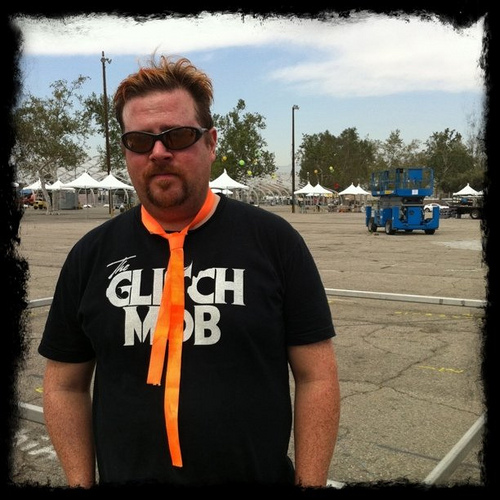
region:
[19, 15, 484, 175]
clouds in daytime sky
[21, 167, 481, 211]
white tops of tents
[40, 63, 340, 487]
man in black tee shirt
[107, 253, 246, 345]
white logo on black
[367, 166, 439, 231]
back of blue utility vehicle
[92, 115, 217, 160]
sun glasses on face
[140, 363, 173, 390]
jagged end of orange tie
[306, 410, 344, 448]
hair on man's arm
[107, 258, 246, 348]
white words on front of shirt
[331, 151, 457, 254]
blue truck in the open area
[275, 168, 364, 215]
tall white tents in the background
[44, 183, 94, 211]
porta potty in the area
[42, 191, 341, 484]
man standing wearing black tee shirt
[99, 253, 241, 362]
white writing on black tee shirt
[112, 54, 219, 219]
man has short golden brown hair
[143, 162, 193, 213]
mustach and partial beard on man's face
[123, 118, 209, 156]
man wearing dark black sunglasses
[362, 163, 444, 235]
double level blue vehicle in distance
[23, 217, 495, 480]
grey parking lot with white lines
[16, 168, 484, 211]
row of white umbrellas in background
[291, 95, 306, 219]
black street lamp with one lamp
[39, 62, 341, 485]
man in black shirt wearing a tie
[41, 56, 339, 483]
man wearing glasses has a goatee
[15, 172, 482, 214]
multiple umbrellas opened in the background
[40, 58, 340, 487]
man wearing a black tee shirt with white letters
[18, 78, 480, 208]
many trees are behind the umbrellas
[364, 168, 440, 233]
blue equipment trucked parked in the lot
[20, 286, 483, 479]
white lines are painted on the ground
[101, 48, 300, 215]
two street lights are on the lot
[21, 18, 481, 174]
faded clouds in the sky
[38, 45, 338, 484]
man's hair is blowing in the wind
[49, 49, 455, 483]
this is a man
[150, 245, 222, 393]
the tie is orange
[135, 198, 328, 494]
the shirt is black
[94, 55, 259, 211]
the man is frowning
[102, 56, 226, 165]
the hair is blonde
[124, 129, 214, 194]
the man has sunglasses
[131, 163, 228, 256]
the man has a goatee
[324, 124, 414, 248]
the vehicle is blue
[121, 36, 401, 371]
a man wearing sunglasses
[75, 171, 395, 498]
a man wearing a shirt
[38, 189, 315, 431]
a man wearing t shirt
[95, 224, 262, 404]
a man with lettering on his shirt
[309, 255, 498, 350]
a white line on the pavement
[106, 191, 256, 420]
a man with an orange tie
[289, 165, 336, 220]
a white tent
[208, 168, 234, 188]
a white tent top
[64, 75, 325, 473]
A person is standing up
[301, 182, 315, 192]
An umbrella on a pole.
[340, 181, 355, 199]
An umbrella on a pole.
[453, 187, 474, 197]
An umbrella on a pole.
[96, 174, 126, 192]
An umbrella on a pole.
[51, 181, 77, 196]
An umbrella on a pole.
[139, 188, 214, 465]
orange ribbon around a man's neck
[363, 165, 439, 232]
blue vehicle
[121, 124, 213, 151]
dark black sun glasses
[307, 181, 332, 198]
open white shade umbrella